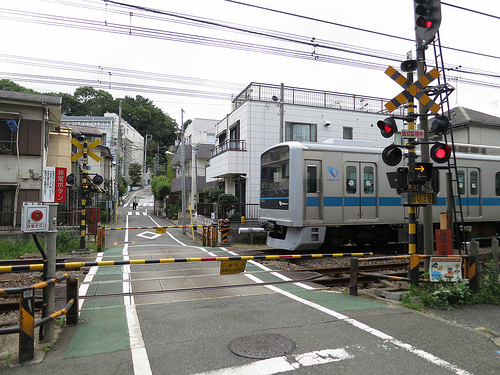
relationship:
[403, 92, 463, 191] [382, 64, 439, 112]
flash lights at crossing sign